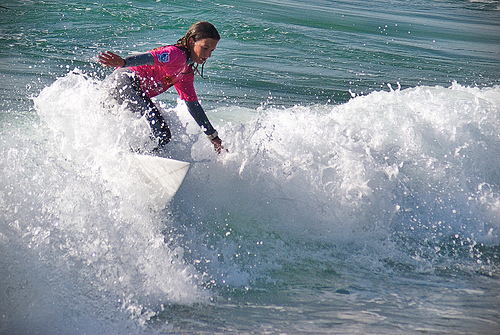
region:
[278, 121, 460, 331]
huge splash of water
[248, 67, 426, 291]
huge splash of water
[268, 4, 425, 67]
The water is blue.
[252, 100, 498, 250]
The waves are white.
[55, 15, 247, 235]
The person is surfing.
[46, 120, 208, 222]
The surfboard is white.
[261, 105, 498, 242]
The waves are splashing.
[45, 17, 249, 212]
The person is wet.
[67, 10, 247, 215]
The person is wearing pink.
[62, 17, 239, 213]
The person is wearing a wetsuit.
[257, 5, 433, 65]
The water is blue green.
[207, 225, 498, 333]
The water has foam in it.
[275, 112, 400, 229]
big splash of water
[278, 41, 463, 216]
big splash of water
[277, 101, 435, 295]
big splash of water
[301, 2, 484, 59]
this is the water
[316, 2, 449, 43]
the water is in motion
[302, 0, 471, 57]
the water is blue in color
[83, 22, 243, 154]
this is a woman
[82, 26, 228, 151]
the woman is on the surfboard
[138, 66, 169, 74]
the surfboard is pink in color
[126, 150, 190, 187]
this is a surfboard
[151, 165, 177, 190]
the surfboard is white in color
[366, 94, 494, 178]
this is raised water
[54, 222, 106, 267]
the water is white in color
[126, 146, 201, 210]
The surfboard is white.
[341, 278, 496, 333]
The water is grey.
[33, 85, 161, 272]
The wave is white.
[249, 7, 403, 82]
The water is bluish green.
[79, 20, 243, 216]
Surfer is a girl.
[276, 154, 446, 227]
The wave is rising.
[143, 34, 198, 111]
The shirt is pink.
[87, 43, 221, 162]
The wetsuit is grey.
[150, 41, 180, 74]
Blue logo on the shirt.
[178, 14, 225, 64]
The surfer has brown hair.